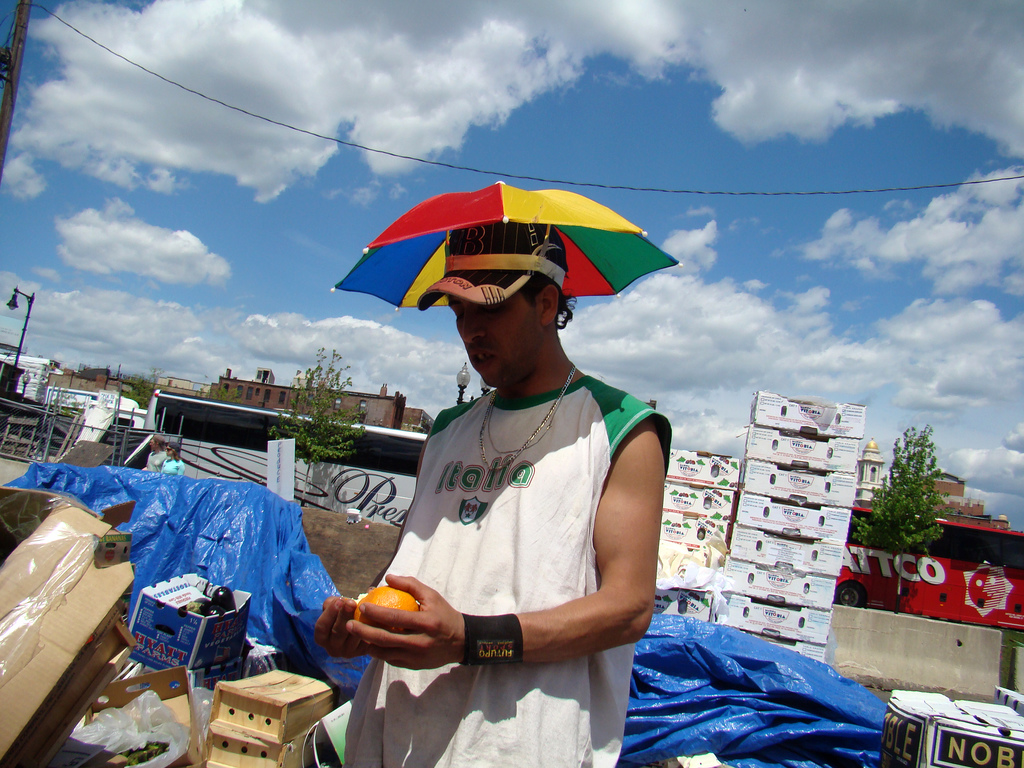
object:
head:
[443, 219, 574, 386]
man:
[318, 223, 676, 764]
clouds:
[221, 308, 470, 388]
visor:
[415, 257, 535, 308]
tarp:
[47, 445, 343, 675]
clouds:
[0, 164, 63, 205]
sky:
[32, 22, 1021, 256]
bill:
[403, 258, 520, 319]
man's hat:
[403, 195, 616, 347]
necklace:
[477, 391, 575, 465]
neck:
[510, 324, 586, 402]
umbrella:
[336, 169, 678, 299]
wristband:
[451, 605, 544, 675]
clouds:
[882, 325, 926, 377]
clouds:
[663, 273, 726, 340]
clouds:
[671, 66, 921, 145]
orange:
[358, 579, 413, 627]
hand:
[350, 575, 471, 664]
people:
[155, 447, 194, 476]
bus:
[860, 508, 1021, 604]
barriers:
[841, 597, 1003, 708]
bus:
[153, 385, 440, 515]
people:
[135, 435, 168, 473]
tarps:
[652, 618, 909, 762]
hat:
[409, 225, 571, 305]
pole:
[5, 4, 32, 158]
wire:
[32, 5, 991, 203]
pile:
[665, 390, 873, 661]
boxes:
[692, 492, 843, 533]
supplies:
[723, 385, 870, 433]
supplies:
[662, 444, 742, 483]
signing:
[876, 707, 926, 759]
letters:
[870, 705, 891, 749]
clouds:
[98, 9, 334, 177]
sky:
[3, 1, 992, 384]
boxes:
[677, 561, 871, 602]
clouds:
[49, 204, 235, 300]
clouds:
[915, 289, 994, 381]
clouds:
[961, 449, 1013, 484]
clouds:
[529, 4, 663, 81]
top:
[336, 367, 667, 763]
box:
[870, 665, 1021, 761]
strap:
[424, 243, 599, 295]